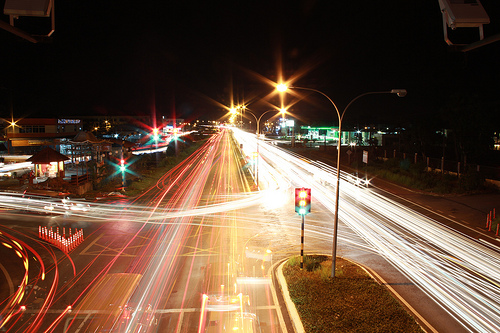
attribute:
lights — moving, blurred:
[150, 195, 269, 253]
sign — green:
[358, 150, 370, 165]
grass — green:
[305, 276, 366, 311]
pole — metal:
[344, 146, 354, 166]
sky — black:
[5, 3, 499, 128]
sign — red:
[158, 118, 193, 141]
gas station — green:
[296, 118, 376, 151]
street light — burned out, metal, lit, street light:
[275, 75, 412, 279]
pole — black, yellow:
[300, 214, 309, 269]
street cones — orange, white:
[37, 224, 87, 250]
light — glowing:
[117, 165, 127, 170]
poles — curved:
[287, 84, 392, 119]